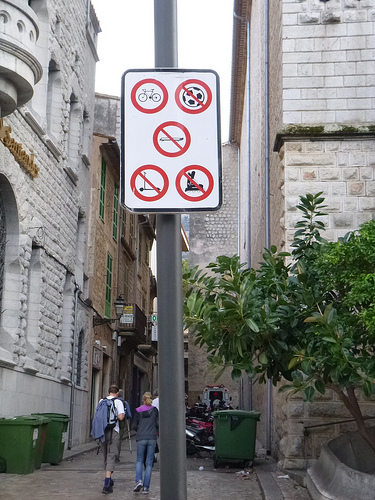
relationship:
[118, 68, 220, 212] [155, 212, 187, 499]
sign on pole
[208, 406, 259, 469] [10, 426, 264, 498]
dumpster on alley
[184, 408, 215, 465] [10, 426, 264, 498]
bike in alley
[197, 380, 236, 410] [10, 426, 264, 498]
vehicle in alley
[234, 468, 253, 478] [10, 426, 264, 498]
litter in alley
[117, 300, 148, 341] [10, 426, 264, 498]
balcony in alley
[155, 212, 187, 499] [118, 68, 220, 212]
pole with sign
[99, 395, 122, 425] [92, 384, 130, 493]
backpack on person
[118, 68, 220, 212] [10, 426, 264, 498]
sign in alley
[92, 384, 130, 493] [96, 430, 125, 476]
person in capris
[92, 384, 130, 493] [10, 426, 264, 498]
person in alley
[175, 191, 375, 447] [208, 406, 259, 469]
tree by dumpster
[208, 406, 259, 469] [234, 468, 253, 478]
dumpster for litter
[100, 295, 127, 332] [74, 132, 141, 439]
light on building